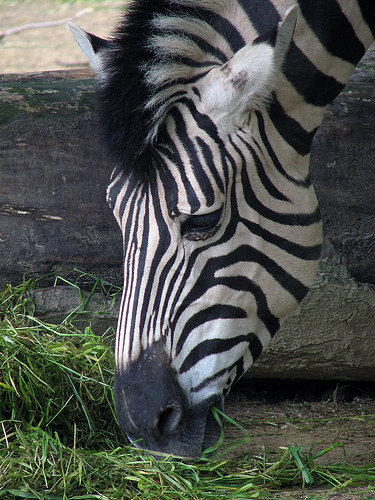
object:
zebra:
[61, 0, 374, 469]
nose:
[110, 348, 188, 448]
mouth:
[191, 393, 225, 467]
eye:
[176, 197, 231, 242]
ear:
[214, 0, 302, 121]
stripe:
[263, 87, 321, 157]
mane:
[92, 0, 234, 189]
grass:
[30, 334, 89, 402]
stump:
[28, 280, 120, 325]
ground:
[11, 445, 97, 492]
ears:
[68, 17, 122, 85]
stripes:
[193, 134, 226, 198]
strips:
[233, 130, 294, 204]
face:
[104, 141, 330, 468]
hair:
[204, 23, 291, 132]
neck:
[231, 0, 375, 152]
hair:
[182, 202, 224, 231]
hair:
[293, 63, 311, 90]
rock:
[45, 280, 83, 327]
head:
[65, 0, 331, 464]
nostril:
[154, 393, 184, 440]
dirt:
[312, 327, 355, 380]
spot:
[150, 66, 215, 95]